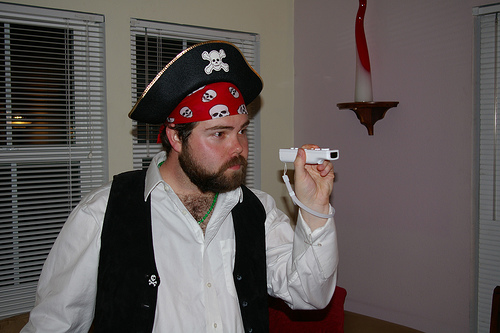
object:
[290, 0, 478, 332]
wall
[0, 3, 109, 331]
blinds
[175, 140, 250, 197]
beard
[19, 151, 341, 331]
shirt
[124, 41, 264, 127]
hat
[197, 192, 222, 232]
necklace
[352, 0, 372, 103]
statue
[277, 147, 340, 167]
console remote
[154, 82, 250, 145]
bandana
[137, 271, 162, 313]
pin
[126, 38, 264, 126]
trim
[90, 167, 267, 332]
vest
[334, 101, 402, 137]
shelf